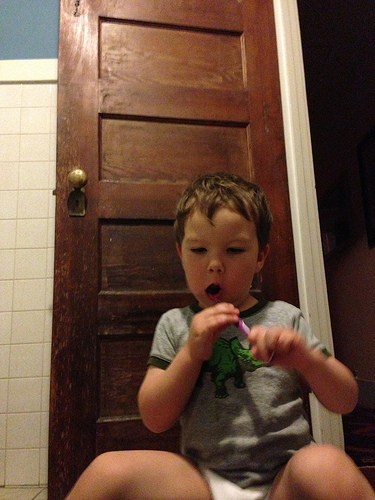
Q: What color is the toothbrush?
A: Purple.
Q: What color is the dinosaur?
A: Green.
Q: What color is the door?
A: Brown.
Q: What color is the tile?
A: White.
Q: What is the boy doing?
A: Brushing his teeth.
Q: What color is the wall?
A: Blue.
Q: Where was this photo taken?
A: The bathroom.